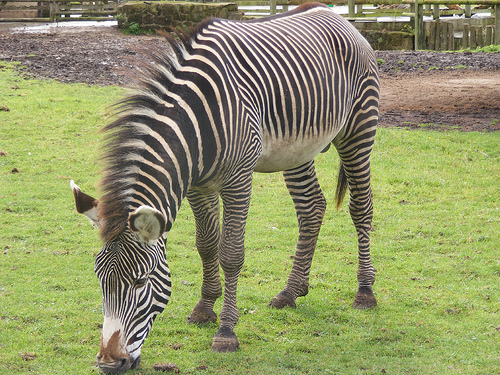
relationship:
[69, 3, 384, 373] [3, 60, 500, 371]
zebra eating grass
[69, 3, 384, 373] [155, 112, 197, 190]
zebra has stripes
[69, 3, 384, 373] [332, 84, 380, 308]
zebra has legs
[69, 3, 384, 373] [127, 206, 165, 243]
zebra has ears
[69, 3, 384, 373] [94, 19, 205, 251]
zebra has mane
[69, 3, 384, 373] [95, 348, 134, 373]
zebra has nose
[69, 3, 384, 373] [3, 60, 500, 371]
zebra feeding on grass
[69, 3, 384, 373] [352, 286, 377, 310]
zebra has hooves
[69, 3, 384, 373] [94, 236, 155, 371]
zebra has face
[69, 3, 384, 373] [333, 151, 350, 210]
zebra has tail